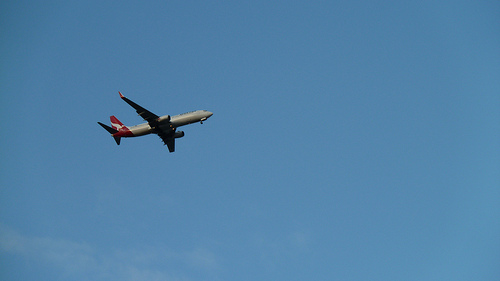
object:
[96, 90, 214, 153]
airplane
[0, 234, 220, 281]
clouds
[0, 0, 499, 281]
sky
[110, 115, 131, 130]
tail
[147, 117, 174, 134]
underbelly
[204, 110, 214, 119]
nose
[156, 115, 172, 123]
engine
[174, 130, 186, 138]
engine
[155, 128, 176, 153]
wing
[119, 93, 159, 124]
wing